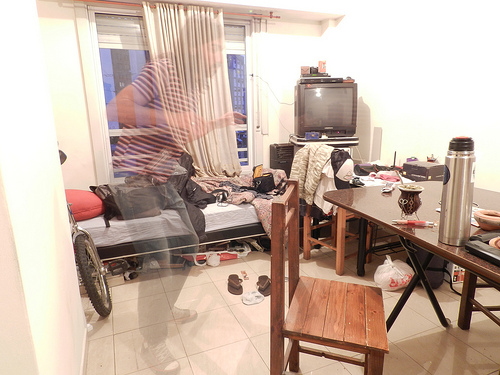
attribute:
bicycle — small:
[67, 201, 115, 326]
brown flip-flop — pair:
[226, 274, 245, 299]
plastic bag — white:
[371, 254, 416, 295]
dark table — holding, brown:
[322, 174, 499, 294]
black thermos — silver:
[435, 131, 477, 246]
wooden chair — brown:
[260, 172, 390, 373]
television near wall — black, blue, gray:
[287, 80, 360, 141]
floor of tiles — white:
[0, 249, 498, 374]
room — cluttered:
[20, 59, 498, 374]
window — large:
[96, 62, 268, 175]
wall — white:
[18, 147, 86, 343]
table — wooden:
[316, 183, 426, 242]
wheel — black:
[75, 233, 111, 314]